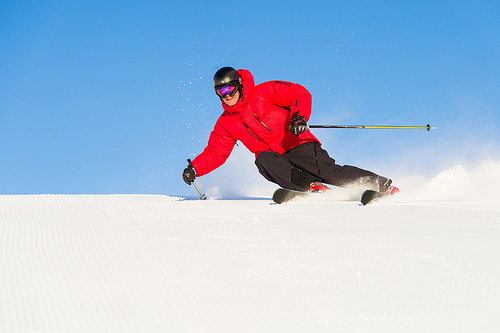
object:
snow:
[0, 205, 499, 332]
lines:
[0, 194, 497, 209]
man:
[183, 66, 401, 204]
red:
[190, 69, 401, 196]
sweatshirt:
[190, 69, 322, 177]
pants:
[254, 141, 392, 194]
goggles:
[214, 80, 241, 97]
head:
[214, 66, 242, 106]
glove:
[289, 116, 307, 137]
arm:
[183, 118, 238, 185]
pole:
[309, 125, 438, 132]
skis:
[273, 187, 328, 205]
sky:
[0, 0, 184, 193]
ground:
[1, 194, 500, 331]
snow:
[420, 171, 500, 197]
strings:
[240, 124, 265, 142]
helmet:
[214, 66, 242, 88]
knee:
[255, 150, 278, 171]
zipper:
[251, 112, 272, 134]